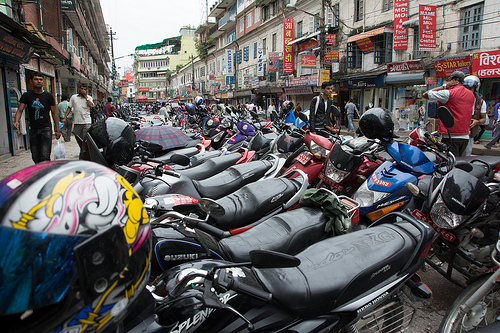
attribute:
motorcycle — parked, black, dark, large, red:
[142, 145, 308, 178]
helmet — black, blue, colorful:
[6, 156, 160, 299]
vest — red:
[441, 83, 481, 138]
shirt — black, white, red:
[69, 97, 101, 123]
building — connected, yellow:
[135, 25, 213, 91]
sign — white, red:
[420, 5, 439, 51]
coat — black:
[311, 100, 336, 129]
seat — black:
[194, 144, 245, 186]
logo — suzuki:
[164, 245, 204, 265]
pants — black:
[28, 126, 61, 166]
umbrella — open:
[251, 85, 300, 116]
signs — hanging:
[289, 23, 435, 63]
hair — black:
[31, 72, 54, 80]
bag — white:
[52, 137, 74, 160]